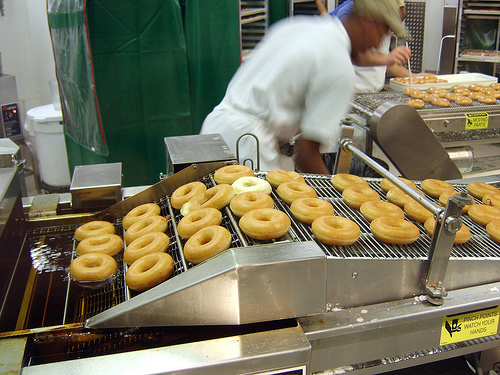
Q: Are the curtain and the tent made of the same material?
A: Yes, both the curtain and the tent are made of plastic.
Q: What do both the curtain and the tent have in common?
A: The material, both the curtain and the tent are plastic.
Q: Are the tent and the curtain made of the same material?
A: Yes, both the tent and the curtain are made of plastic.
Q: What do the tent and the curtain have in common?
A: The material, both the tent and the curtain are plastic.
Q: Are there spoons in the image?
A: Yes, there is a spoon.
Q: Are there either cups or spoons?
A: Yes, there is a spoon.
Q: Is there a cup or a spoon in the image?
A: Yes, there is a spoon.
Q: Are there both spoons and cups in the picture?
A: No, there is a spoon but no cups.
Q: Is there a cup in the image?
A: No, there are no cups.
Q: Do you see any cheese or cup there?
A: No, there are no cups or cheese.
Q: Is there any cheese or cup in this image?
A: No, there are no cups or cheese.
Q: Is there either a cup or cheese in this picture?
A: No, there are no cups or cheese.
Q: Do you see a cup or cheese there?
A: No, there are no cups or cheese.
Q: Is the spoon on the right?
A: Yes, the spoon is on the right of the image.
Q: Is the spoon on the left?
A: No, the spoon is on the right of the image.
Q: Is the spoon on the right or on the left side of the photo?
A: The spoon is on the right of the image.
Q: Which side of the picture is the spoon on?
A: The spoon is on the right of the image.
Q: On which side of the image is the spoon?
A: The spoon is on the right of the image.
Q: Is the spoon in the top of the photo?
A: Yes, the spoon is in the top of the image.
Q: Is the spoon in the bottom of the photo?
A: No, the spoon is in the top of the image.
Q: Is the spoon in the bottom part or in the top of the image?
A: The spoon is in the top of the image.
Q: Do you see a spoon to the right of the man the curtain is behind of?
A: Yes, there is a spoon to the right of the man.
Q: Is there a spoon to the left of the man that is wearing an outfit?
A: No, the spoon is to the right of the man.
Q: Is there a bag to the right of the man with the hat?
A: No, there is a spoon to the right of the man.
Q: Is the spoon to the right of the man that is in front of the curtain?
A: Yes, the spoon is to the right of the man.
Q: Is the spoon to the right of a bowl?
A: No, the spoon is to the right of the man.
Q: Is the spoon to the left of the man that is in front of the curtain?
A: No, the spoon is to the right of the man.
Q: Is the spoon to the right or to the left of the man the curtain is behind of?
A: The spoon is to the right of the man.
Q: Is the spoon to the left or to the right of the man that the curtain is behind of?
A: The spoon is to the right of the man.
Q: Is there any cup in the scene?
A: No, there are no cups.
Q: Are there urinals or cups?
A: No, there are no cups or urinals.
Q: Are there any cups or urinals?
A: No, there are no cups or urinals.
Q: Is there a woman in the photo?
A: No, there are no women.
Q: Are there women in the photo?
A: No, there are no women.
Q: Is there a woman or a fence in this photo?
A: No, there are no women or fences.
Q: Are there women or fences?
A: No, there are no women or fences.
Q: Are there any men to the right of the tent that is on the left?
A: Yes, there is a man to the right of the tent.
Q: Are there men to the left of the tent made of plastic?
A: No, the man is to the right of the tent.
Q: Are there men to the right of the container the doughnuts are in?
A: No, the man is to the left of the container.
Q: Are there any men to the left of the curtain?
A: No, the man is to the right of the curtain.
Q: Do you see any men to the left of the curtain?
A: No, the man is to the right of the curtain.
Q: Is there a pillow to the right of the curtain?
A: No, there is a man to the right of the curtain.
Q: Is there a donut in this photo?
A: Yes, there is a donut.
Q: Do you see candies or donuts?
A: Yes, there is a donut.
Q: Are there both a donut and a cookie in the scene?
A: No, there is a donut but no cookies.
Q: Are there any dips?
A: No, there are no dips.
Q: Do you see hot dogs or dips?
A: No, there are no dips or hot dogs.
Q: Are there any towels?
A: No, there are no towels.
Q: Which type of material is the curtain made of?
A: The curtain is made of plastic.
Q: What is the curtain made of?
A: The curtain is made of plastic.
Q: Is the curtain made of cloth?
A: No, the curtain is made of plastic.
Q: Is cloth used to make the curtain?
A: No, the curtain is made of plastic.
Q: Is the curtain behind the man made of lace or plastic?
A: The curtain is made of plastic.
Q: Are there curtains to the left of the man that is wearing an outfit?
A: Yes, there is a curtain to the left of the man.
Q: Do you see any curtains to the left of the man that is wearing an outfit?
A: Yes, there is a curtain to the left of the man.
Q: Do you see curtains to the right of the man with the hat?
A: No, the curtain is to the left of the man.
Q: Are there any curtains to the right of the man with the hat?
A: No, the curtain is to the left of the man.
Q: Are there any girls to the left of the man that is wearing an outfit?
A: No, there is a curtain to the left of the man.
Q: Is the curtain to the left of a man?
A: Yes, the curtain is to the left of a man.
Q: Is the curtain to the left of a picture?
A: No, the curtain is to the left of a man.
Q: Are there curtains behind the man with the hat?
A: Yes, there is a curtain behind the man.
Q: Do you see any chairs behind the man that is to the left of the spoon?
A: No, there is a curtain behind the man.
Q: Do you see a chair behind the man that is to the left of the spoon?
A: No, there is a curtain behind the man.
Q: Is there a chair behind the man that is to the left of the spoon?
A: No, there is a curtain behind the man.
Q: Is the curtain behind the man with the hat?
A: Yes, the curtain is behind the man.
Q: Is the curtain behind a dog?
A: No, the curtain is behind the man.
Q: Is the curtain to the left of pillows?
A: No, the curtain is to the left of the donuts.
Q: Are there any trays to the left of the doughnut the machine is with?
A: No, there is a curtain to the left of the donut.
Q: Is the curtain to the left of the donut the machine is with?
A: Yes, the curtain is to the left of the doughnut.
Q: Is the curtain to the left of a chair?
A: No, the curtain is to the left of the doughnut.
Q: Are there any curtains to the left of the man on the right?
A: Yes, there is a curtain to the left of the man.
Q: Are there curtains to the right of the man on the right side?
A: No, the curtain is to the left of the man.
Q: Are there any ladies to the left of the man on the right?
A: No, there is a curtain to the left of the man.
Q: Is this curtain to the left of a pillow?
A: No, the curtain is to the left of a man.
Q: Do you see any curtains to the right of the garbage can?
A: Yes, there is a curtain to the right of the garbage can.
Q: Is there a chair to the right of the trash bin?
A: No, there is a curtain to the right of the trash bin.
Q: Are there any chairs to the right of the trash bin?
A: No, there is a curtain to the right of the trash bin.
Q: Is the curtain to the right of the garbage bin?
A: Yes, the curtain is to the right of the garbage bin.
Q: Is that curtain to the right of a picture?
A: No, the curtain is to the right of the garbage bin.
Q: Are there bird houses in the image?
A: No, there are no bird houses.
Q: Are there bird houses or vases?
A: No, there are no bird houses or vases.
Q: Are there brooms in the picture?
A: No, there are no brooms.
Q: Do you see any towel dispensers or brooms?
A: No, there are no brooms or towel dispensers.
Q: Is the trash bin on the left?
A: Yes, the trash bin is on the left of the image.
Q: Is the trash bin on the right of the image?
A: No, the trash bin is on the left of the image.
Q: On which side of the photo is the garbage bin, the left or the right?
A: The garbage bin is on the left of the image.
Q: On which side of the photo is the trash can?
A: The trash can is on the left of the image.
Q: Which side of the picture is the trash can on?
A: The trash can is on the left of the image.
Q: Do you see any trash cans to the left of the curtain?
A: Yes, there is a trash can to the left of the curtain.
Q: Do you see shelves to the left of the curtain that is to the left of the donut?
A: No, there is a trash can to the left of the curtain.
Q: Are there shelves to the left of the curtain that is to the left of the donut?
A: No, there is a trash can to the left of the curtain.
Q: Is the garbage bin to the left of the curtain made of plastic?
A: Yes, the garbage bin is to the left of the curtain.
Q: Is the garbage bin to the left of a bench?
A: No, the garbage bin is to the left of the curtain.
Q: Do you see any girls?
A: No, there are no girls.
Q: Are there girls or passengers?
A: No, there are no girls or passengers.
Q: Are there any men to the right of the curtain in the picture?
A: Yes, there is a man to the right of the curtain.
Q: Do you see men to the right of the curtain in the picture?
A: Yes, there is a man to the right of the curtain.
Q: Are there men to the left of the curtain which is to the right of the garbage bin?
A: No, the man is to the right of the curtain.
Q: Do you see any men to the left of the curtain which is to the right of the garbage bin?
A: No, the man is to the right of the curtain.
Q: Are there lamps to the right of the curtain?
A: No, there is a man to the right of the curtain.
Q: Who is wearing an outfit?
A: The man is wearing an outfit.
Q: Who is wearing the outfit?
A: The man is wearing an outfit.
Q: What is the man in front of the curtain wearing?
A: The man is wearing an outfit.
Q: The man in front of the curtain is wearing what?
A: The man is wearing an outfit.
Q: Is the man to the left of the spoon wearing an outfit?
A: Yes, the man is wearing an outfit.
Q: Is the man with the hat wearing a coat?
A: No, the man is wearing an outfit.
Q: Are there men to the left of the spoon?
A: Yes, there is a man to the left of the spoon.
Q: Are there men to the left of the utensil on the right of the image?
A: Yes, there is a man to the left of the spoon.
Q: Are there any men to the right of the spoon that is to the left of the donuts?
A: No, the man is to the left of the spoon.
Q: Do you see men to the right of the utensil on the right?
A: No, the man is to the left of the spoon.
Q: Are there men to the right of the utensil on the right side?
A: No, the man is to the left of the spoon.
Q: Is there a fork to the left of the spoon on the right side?
A: No, there is a man to the left of the spoon.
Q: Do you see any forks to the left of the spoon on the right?
A: No, there is a man to the left of the spoon.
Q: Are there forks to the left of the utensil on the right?
A: No, there is a man to the left of the spoon.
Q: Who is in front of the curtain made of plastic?
A: The man is in front of the curtain.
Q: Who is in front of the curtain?
A: The man is in front of the curtain.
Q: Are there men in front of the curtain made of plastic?
A: Yes, there is a man in front of the curtain.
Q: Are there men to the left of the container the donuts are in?
A: Yes, there is a man to the left of the container.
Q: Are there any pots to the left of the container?
A: No, there is a man to the left of the container.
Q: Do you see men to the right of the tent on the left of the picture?
A: Yes, there is a man to the right of the tent.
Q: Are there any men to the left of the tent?
A: No, the man is to the right of the tent.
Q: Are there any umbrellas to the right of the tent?
A: No, there is a man to the right of the tent.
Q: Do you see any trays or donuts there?
A: Yes, there are donuts.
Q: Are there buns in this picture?
A: No, there are no buns.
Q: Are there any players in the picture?
A: No, there are no players.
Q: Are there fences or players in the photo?
A: No, there are no players or fences.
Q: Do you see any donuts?
A: Yes, there is a donut.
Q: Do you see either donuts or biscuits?
A: Yes, there is a donut.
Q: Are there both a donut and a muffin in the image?
A: No, there is a donut but no muffins.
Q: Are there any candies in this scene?
A: No, there are no candies.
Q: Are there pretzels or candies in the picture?
A: No, there are no candies or pretzels.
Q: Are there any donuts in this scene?
A: Yes, there is a donut.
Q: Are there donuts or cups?
A: Yes, there is a donut.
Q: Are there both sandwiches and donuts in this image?
A: No, there is a donut but no sandwiches.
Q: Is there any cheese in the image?
A: No, there is no cheese.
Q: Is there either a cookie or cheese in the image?
A: No, there are no cheese or cookies.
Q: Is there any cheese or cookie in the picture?
A: No, there are no cheese or cookies.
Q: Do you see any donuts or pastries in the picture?
A: Yes, there is a donut.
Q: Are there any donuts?
A: Yes, there is a donut.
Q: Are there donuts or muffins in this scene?
A: Yes, there is a donut.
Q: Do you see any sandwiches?
A: No, there are no sandwiches.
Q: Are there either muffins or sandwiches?
A: No, there are no sandwiches or muffins.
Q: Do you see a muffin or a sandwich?
A: No, there are no sandwiches or muffins.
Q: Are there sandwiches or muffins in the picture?
A: No, there are no sandwiches or muffins.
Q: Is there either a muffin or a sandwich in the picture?
A: No, there are no sandwiches or muffins.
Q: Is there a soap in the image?
A: No, there are no soaps.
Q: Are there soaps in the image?
A: No, there are no soaps.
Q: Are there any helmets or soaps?
A: No, there are no soaps or helmets.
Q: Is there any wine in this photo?
A: No, there is no wine.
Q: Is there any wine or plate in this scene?
A: No, there are no wine or plates.